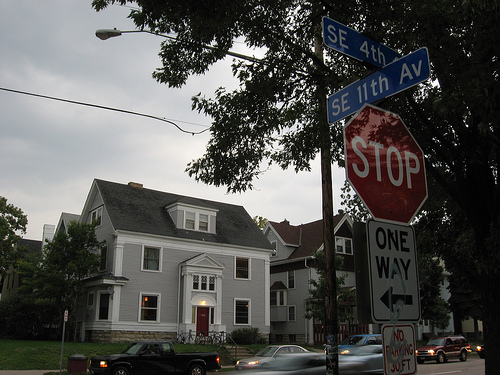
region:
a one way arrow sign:
[362, 214, 425, 325]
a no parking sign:
[378, 324, 420, 374]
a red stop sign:
[345, 106, 432, 226]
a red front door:
[193, 299, 215, 339]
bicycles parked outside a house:
[178, 328, 235, 348]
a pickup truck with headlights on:
[81, 336, 228, 373]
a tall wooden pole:
[308, 4, 350, 372]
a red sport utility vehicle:
[416, 329, 473, 362]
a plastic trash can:
[68, 350, 87, 373]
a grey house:
[69, 170, 274, 345]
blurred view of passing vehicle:
[268, 355, 300, 373]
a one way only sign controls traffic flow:
[373, 225, 418, 318]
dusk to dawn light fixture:
[92, 18, 135, 47]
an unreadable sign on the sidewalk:
[60, 305, 70, 368]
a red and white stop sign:
[349, 127, 426, 203]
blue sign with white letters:
[325, 18, 387, 65]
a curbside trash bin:
[67, 350, 89, 373]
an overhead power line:
[5, 73, 150, 135]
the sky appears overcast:
[6, 123, 151, 171]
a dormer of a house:
[162, 192, 233, 237]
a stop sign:
[326, 100, 455, 228]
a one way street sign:
[354, 205, 445, 344]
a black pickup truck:
[74, 330, 234, 372]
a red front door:
[181, 297, 233, 345]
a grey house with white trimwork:
[52, 165, 287, 352]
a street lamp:
[78, 13, 145, 64]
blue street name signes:
[285, 3, 459, 145]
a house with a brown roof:
[252, 199, 374, 281]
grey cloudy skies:
[7, 1, 365, 187]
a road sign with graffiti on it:
[333, 202, 467, 340]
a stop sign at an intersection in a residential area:
[339, 101, 436, 231]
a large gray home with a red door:
[64, 170, 286, 353]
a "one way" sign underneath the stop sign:
[365, 211, 430, 323]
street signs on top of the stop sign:
[315, 13, 447, 110]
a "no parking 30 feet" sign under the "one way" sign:
[382, 321, 422, 371]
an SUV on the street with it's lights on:
[419, 335, 474, 367]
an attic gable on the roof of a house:
[168, 194, 224, 234]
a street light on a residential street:
[81, 16, 150, 54]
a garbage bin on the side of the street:
[67, 353, 89, 370]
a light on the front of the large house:
[198, 299, 209, 306]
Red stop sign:
[341, 104, 438, 229]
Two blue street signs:
[311, 7, 436, 111]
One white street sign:
[364, 215, 430, 322]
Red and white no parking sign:
[377, 318, 426, 373]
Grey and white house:
[73, 178, 275, 345]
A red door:
[191, 296, 223, 345]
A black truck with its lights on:
[88, 337, 227, 373]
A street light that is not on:
[88, 18, 352, 99]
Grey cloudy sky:
[9, 44, 161, 179]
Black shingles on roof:
[84, 169, 283, 262]